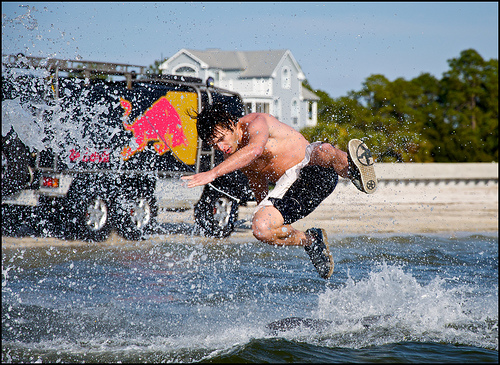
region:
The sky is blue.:
[0, 0, 498, 107]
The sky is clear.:
[1, 0, 498, 127]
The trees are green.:
[298, 45, 498, 160]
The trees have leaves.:
[298, 48, 498, 161]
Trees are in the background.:
[302, 45, 499, 160]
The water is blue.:
[3, 230, 497, 361]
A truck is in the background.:
[1, 53, 249, 239]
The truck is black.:
[1, 54, 253, 236]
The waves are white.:
[316, 262, 462, 339]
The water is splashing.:
[313, 262, 465, 339]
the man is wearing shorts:
[257, 143, 344, 224]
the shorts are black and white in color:
[262, 143, 341, 227]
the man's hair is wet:
[187, 103, 237, 145]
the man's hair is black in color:
[190, 100, 239, 138]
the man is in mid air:
[184, 102, 377, 281]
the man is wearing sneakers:
[303, 226, 335, 282]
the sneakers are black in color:
[306, 225, 336, 282]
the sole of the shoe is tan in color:
[348, 138, 376, 194]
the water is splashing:
[7, 13, 495, 360]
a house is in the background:
[155, 45, 317, 147]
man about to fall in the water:
[183, 93, 386, 303]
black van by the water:
[0, 62, 267, 233]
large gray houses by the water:
[154, 41, 324, 136]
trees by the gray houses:
[295, 48, 499, 164]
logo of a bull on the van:
[101, 93, 191, 164]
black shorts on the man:
[258, 158, 340, 225]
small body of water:
[0, 224, 499, 363]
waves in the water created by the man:
[4, 253, 496, 363]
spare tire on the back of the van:
[0, 140, 32, 196]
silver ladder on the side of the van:
[190, 78, 220, 186]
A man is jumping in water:
[207, 105, 387, 298]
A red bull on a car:
[91, 79, 204, 168]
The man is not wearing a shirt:
[203, 103, 313, 201]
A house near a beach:
[175, 45, 322, 137]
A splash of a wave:
[341, 270, 454, 350]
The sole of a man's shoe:
[344, 138, 379, 200]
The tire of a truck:
[86, 192, 120, 250]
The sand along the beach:
[412, 192, 498, 245]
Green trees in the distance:
[383, 75, 498, 159]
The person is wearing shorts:
[242, 124, 375, 274]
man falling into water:
[161, 85, 422, 299]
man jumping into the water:
[176, 75, 388, 284]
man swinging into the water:
[171, 72, 400, 286]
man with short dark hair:
[157, 92, 399, 294]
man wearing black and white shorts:
[169, 92, 389, 287]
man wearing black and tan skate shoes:
[159, 82, 396, 287]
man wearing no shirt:
[167, 95, 387, 290]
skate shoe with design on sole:
[339, 129, 387, 198]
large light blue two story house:
[155, 35, 326, 135]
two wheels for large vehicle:
[68, 171, 164, 243]